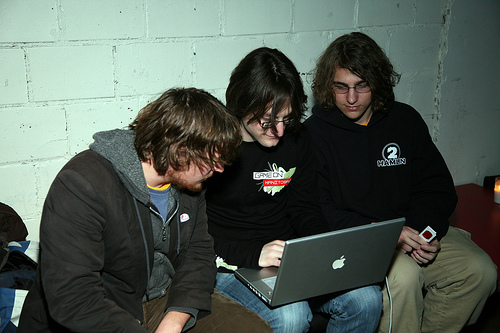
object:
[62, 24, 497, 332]
men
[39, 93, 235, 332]
man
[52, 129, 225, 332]
hoody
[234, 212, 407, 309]
computer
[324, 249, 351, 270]
logo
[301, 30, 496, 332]
boy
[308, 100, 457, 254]
hoody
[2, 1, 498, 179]
cinder blocks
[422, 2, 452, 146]
crack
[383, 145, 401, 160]
number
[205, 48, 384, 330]
man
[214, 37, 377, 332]
middle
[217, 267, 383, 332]
jeans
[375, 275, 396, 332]
power cord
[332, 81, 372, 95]
glasses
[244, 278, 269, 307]
ports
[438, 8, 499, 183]
cinder blocks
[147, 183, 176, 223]
tee shirt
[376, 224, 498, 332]
pants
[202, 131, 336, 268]
sweat shirt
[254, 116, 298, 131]
eye glasses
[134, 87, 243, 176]
hair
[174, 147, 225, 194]
face